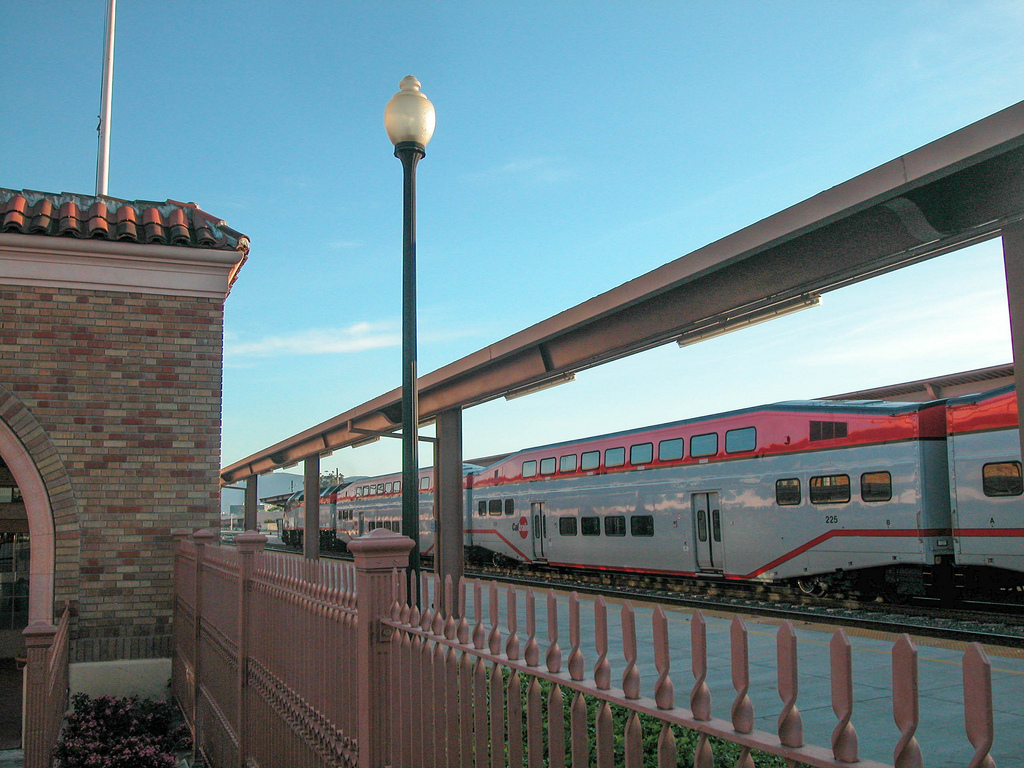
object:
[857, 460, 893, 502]
window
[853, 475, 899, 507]
window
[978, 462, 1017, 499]
window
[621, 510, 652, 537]
window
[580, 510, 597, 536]
window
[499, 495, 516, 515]
window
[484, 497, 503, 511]
window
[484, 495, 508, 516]
window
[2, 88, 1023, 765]
train station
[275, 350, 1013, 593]
passenger train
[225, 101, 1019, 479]
overhang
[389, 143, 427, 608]
pole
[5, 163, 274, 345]
roof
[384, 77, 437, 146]
bulb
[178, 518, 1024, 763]
fence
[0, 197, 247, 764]
archway